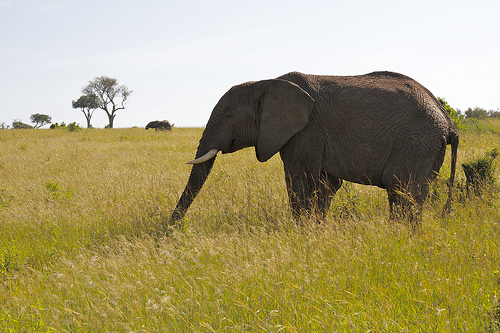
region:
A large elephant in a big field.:
[161, 66, 461, 234]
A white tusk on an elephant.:
[185, 146, 220, 168]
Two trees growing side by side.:
[72, 75, 132, 133]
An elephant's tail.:
[437, 128, 461, 220]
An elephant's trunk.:
[168, 143, 220, 228]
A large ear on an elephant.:
[252, 78, 314, 162]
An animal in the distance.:
[141, 117, 177, 134]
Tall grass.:
[0, 114, 498, 331]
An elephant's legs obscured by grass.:
[281, 159, 433, 234]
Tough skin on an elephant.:
[164, 68, 459, 235]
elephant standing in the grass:
[154, 65, 475, 253]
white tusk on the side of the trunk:
[182, 150, 228, 166]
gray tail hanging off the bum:
[444, 118, 464, 218]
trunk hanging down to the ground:
[152, 139, 233, 245]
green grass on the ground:
[7, 128, 499, 327]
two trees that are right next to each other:
[65, 72, 132, 134]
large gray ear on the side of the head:
[251, 86, 317, 163]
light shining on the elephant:
[418, 93, 453, 138]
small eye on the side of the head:
[218, 109, 233, 121]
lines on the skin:
[314, 101, 344, 132]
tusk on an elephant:
[185, 145, 225, 170]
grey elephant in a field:
[144, 70, 479, 244]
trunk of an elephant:
[156, 133, 221, 235]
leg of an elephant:
[280, 155, 322, 227]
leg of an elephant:
[305, 171, 342, 228]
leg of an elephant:
[384, 164, 441, 239]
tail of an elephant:
[444, 126, 463, 216]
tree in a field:
[80, 72, 137, 129]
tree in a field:
[67, 91, 103, 130]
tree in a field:
[26, 106, 53, 133]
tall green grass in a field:
[12, 131, 174, 314]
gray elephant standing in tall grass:
[159, 65, 463, 237]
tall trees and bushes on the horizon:
[0, 77, 135, 139]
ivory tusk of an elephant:
[182, 147, 221, 168]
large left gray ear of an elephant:
[255, 77, 317, 163]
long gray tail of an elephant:
[444, 114, 460, 225]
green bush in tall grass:
[464, 148, 497, 196]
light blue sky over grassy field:
[44, 8, 285, 78]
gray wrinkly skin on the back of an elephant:
[305, 69, 448, 119]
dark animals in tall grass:
[139, 114, 185, 135]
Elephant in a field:
[164, 44, 469, 287]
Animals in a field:
[142, 111, 184, 139]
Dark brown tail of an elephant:
[438, 111, 463, 230]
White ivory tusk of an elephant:
[185, 149, 227, 166]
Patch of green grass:
[20, 264, 112, 331]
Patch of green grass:
[122, 258, 180, 331]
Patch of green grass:
[198, 257, 264, 329]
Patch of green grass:
[294, 255, 336, 331]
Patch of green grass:
[342, 250, 390, 327]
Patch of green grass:
[408, 255, 471, 319]